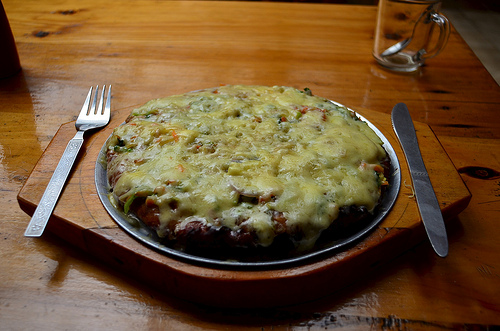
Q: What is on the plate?
A: Food.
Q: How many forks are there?
A: One.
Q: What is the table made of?
A: Wood.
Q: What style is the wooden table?
A: Rustic.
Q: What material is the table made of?
A: Wood.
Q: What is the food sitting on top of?
A: Wooden table.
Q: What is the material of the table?
A: Wood.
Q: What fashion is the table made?
A: Rustic.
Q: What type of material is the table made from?
A: Wood.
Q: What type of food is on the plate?
A: Frittata.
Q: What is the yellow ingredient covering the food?
A: Cheese.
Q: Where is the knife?
A: To the right of the plate.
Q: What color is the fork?
A: Silver.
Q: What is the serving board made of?
A: Wood.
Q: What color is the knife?
A: Silver.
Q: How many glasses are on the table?
A: 1.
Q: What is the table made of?
A: Wood.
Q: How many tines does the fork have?
A: 4.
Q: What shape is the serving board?
A: Hexagon.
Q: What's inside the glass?
A: A spoon.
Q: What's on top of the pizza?
A: Melted cheese.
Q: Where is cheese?
A: On the pizza.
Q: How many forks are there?
A: One.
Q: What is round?
A: Pizza pie.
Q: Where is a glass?
A: On the table.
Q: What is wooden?
A: Table.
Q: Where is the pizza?
A: On a pan.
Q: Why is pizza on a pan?
A: To be eaten.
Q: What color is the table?
A: Brown.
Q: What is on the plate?
A: Pizza.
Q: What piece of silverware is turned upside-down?
A: Knife.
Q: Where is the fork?
A: On the left of the pizza.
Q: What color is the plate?
A: Silver.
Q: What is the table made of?
A: Wood.